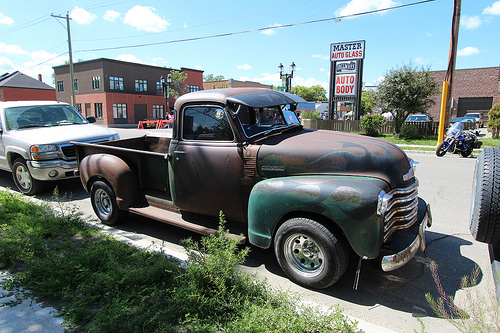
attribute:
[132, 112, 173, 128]
sign — red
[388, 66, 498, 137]
building — brown, red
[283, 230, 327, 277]
spokes — silver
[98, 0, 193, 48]
sky — blue, white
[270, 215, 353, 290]
wheel — chrome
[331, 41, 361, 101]
sign — large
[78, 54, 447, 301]
truck — old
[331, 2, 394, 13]
cloud — white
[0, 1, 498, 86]
sky — blue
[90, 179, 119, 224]
wheel — rear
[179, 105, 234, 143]
window — side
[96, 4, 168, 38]
clouds — white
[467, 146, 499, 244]
tire — spare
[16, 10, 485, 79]
sky — blue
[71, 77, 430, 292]
truck — old